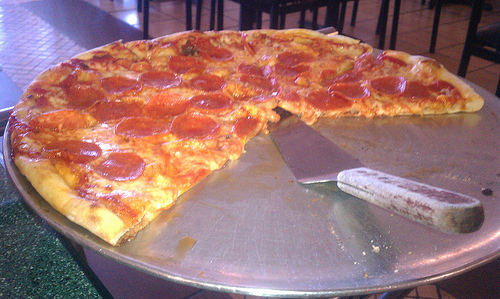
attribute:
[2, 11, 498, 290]
tray — silver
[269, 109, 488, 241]
spatula — silver, metal, wood, wooden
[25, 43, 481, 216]
pizza — tasty, gone, large, cut, pepperoni, hot, slice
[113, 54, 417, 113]
cheese — yellow, orange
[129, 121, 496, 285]
pizzatray — silver, metal, gone, large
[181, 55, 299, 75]
peproni — red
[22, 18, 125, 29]
floor — tiled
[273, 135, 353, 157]
blade — mettalic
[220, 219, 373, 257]
surface — silver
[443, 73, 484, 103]
crust — brown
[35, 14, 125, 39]
tiles — brown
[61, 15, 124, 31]
shadow — darkblue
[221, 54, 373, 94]
pepperoni — shiny, greasy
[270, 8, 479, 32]
chairs — black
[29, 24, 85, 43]
walkway — patterned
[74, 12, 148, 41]
carpet — green